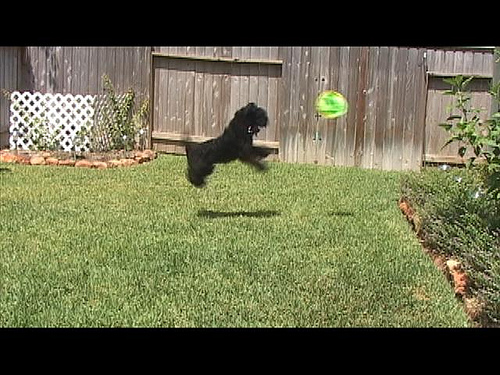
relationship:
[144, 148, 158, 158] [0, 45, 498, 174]
stone in front of fence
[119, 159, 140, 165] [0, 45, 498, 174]
stone in front of fence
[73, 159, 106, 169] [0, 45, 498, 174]
stone in front of fence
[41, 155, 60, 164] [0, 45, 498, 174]
stone in front of fence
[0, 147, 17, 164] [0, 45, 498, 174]
stone in front of fence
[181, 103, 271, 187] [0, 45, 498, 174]
dog by fence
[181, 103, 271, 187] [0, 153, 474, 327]
dog in grass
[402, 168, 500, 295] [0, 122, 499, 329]
shrub in yard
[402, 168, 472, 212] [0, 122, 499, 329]
shrub in yard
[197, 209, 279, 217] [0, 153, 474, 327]
shadow on grass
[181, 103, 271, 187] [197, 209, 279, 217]
dog has shadow